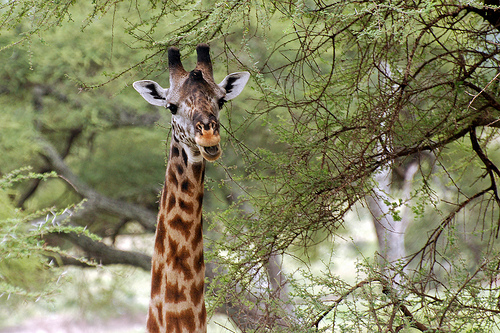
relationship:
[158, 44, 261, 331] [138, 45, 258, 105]
giraffe has ears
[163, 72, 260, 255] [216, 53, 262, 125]
giraffe's ears pointed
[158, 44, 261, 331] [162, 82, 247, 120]
giraffe has two eyes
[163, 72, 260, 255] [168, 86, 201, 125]
giraffe's eyes open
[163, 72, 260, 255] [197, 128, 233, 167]
giraffe's mouth opened slightly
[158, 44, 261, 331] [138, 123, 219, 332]
giraffe has a long neck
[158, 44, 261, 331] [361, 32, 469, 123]
giraffe standing among tree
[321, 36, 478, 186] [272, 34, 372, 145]
tree limbs spindly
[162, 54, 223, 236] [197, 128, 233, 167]
giraffee's open mouth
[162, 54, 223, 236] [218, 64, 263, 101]
giraffee's left ear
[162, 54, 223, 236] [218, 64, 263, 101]
giraffee's right ear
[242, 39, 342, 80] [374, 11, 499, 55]
leaves on of picture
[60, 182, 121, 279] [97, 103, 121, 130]
wooden branches background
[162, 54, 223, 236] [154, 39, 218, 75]
giraffee's left horn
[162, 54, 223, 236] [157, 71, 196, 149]
giraffee's horn side of his head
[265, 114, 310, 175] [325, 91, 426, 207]
dying leaves on branches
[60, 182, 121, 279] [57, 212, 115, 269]
wooden tree trunk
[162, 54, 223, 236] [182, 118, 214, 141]
giraffee's nose above mouth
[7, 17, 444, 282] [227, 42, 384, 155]
picture taken outdoors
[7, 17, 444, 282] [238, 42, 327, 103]
picture taken during the day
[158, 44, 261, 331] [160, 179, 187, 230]
giraffe has brown spots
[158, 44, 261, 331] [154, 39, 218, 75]
giraffe has horns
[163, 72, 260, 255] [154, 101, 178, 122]
giraffe's eyes are black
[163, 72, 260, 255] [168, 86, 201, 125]
giraffe's mouth open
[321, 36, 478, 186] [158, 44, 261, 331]
trees around giraffe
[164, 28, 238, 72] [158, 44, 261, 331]
horns on giraffe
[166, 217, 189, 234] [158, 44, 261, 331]
spot on giraffe